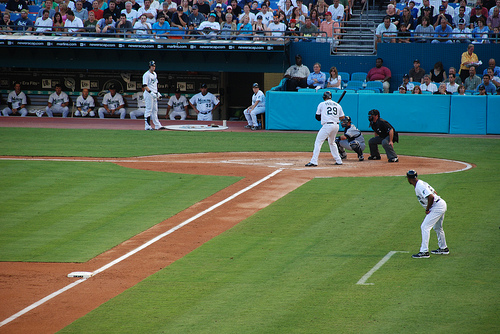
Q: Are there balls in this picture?
A: No, there are no balls.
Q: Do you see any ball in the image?
A: No, there are no balls.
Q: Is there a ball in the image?
A: No, there are no balls.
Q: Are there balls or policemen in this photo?
A: No, there are no balls or policemen.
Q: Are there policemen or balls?
A: No, there are no balls or policemen.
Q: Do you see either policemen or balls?
A: No, there are no balls or policemen.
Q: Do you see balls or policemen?
A: No, there are no balls or policemen.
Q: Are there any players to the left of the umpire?
A: Yes, there is a player to the left of the umpire.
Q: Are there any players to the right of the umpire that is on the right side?
A: No, the player is to the left of the umpire.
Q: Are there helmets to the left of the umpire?
A: No, there is a player to the left of the umpire.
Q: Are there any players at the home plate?
A: Yes, there is a player at the home plate.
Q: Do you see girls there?
A: No, there are no girls.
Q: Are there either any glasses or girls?
A: No, there are no girls or glasses.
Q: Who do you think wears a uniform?
A: The player wears a uniform.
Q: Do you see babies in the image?
A: No, there are no babies.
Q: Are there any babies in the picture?
A: No, there are no babies.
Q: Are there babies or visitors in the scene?
A: No, there are no babies or visitors.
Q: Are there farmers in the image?
A: No, there are no farmers.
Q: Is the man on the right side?
A: Yes, the man is on the right of the image.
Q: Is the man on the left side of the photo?
A: No, the man is on the right of the image.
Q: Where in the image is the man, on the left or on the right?
A: The man is on the right of the image.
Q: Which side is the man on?
A: The man is on the right of the image.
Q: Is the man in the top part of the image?
A: Yes, the man is in the top of the image.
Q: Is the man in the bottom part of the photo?
A: No, the man is in the top of the image.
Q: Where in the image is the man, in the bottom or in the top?
A: The man is in the top of the image.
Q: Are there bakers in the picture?
A: No, there are no bakers.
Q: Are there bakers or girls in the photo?
A: No, there are no bakers or girls.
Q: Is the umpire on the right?
A: Yes, the umpire is on the right of the image.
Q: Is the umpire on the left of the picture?
A: No, the umpire is on the right of the image.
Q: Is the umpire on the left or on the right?
A: The umpire is on the right of the image.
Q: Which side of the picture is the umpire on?
A: The umpire is on the right of the image.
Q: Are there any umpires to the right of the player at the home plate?
A: Yes, there is an umpire to the right of the player.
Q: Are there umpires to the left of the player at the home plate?
A: No, the umpire is to the right of the player.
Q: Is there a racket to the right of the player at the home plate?
A: No, there is an umpire to the right of the player.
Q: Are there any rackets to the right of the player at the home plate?
A: No, there is an umpire to the right of the player.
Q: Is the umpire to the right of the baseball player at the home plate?
A: Yes, the umpire is to the right of the player.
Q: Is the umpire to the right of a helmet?
A: No, the umpire is to the right of the player.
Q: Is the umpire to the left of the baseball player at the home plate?
A: No, the umpire is to the right of the player.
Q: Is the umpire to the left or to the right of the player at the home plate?
A: The umpire is to the right of the player.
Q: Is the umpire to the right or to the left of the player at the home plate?
A: The umpire is to the right of the player.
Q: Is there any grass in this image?
A: Yes, there is grass.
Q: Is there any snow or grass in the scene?
A: Yes, there is grass.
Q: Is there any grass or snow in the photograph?
A: Yes, there is grass.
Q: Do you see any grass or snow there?
A: Yes, there is grass.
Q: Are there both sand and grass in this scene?
A: No, there is grass but no sand.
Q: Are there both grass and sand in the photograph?
A: No, there is grass but no sand.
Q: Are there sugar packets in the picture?
A: No, there are no sugar packets.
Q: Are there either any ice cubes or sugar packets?
A: No, there are no sugar packets or ice cubes.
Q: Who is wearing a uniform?
A: The player is wearing a uniform.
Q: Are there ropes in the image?
A: No, there are no ropes.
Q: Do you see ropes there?
A: No, there are no ropes.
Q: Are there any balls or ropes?
A: No, there are no ropes or balls.